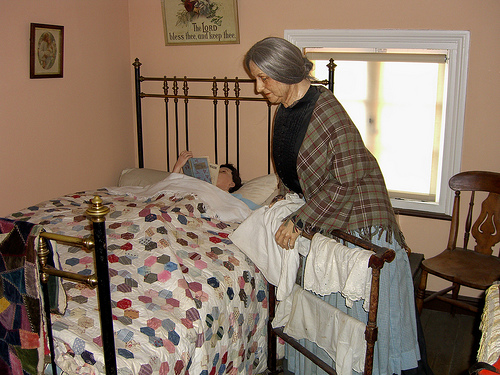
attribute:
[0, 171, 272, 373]
quilt — old, blanket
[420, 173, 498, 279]
lwood chair — wood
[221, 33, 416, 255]
woman — old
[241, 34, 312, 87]
gray hair — grey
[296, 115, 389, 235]
shawl — plaid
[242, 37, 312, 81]
hair — grey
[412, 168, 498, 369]
chair — wooden, brown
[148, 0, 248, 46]
phrase — religious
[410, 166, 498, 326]
chair — made of wood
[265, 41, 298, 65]
hair — grey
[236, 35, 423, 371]
woman — old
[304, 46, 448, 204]
blind — roller blind, shut